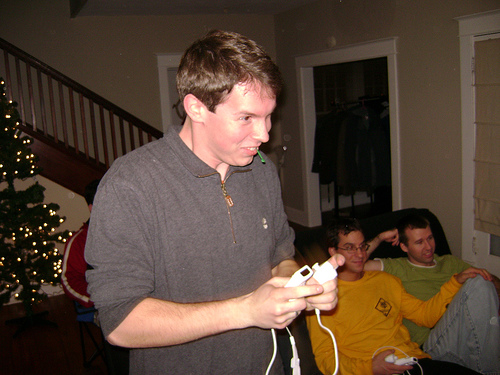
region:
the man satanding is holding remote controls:
[283, 255, 339, 322]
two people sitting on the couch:
[321, 205, 486, 373]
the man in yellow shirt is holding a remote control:
[382, 344, 419, 372]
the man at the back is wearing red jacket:
[56, 177, 94, 318]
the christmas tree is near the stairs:
[3, 82, 73, 332]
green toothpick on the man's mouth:
[245, 141, 269, 165]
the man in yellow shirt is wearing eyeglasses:
[336, 242, 371, 253]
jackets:
[308, 94, 388, 196]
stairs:
[28, 30, 150, 190]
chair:
[73, 310, 108, 371]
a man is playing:
[192, 202, 384, 371]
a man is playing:
[122, 123, 350, 373]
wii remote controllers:
[286, 256, 346, 306]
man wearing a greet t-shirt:
[394, 218, 474, 290]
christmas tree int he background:
[2, 112, 62, 296]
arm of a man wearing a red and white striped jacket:
[63, 227, 89, 314]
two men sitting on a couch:
[316, 211, 451, 365]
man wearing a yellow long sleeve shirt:
[301, 228, 403, 373]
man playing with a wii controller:
[36, 71, 343, 374]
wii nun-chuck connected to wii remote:
[310, 264, 343, 370]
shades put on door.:
[466, 42, 498, 232]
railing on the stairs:
[21, 43, 143, 158]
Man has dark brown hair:
[168, 39, 268, 84]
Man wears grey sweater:
[98, 184, 305, 269]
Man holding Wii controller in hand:
[241, 244, 361, 364]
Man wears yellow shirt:
[336, 279, 412, 351]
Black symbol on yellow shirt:
[366, 293, 400, 327]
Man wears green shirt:
[400, 266, 452, 283]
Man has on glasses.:
[323, 216, 384, 277]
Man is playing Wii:
[70, 43, 353, 373]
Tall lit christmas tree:
[1, 74, 74, 350]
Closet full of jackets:
[305, 54, 403, 220]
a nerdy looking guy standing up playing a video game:
[71, 23, 360, 372]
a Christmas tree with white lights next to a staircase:
[4, 79, 80, 316]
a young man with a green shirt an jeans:
[385, 211, 494, 368]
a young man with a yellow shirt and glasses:
[311, 206, 469, 373]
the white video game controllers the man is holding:
[281, 253, 345, 335]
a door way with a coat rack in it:
[293, 48, 411, 227]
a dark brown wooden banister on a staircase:
[2, 44, 167, 179]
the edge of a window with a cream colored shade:
[445, 7, 499, 264]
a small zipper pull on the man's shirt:
[212, 182, 238, 213]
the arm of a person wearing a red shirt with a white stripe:
[51, 227, 99, 314]